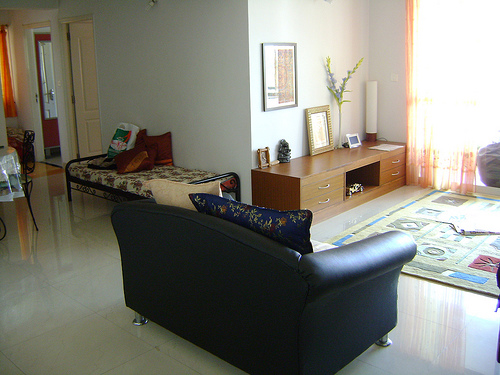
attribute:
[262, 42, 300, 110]
mirror — wooden, framed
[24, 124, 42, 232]
chair — black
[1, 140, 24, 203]
tablecloth — white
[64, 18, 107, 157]
door — white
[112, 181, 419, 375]
couch — black, small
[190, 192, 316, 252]
pillow — blue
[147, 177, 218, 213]
pillow — white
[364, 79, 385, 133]
candle — white, tall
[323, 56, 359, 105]
flowers — yellow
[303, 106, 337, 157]
frame — gold, framed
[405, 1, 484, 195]
curtains — sheer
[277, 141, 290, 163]
figurine — small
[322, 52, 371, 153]
flower — tall